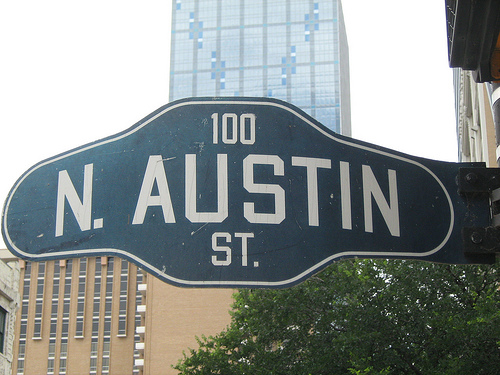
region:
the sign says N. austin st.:
[16, 97, 498, 299]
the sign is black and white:
[1, 88, 499, 313]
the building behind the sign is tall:
[153, 57, 374, 373]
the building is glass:
[161, 3, 371, 163]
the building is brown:
[8, 230, 253, 373]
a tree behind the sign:
[31, 90, 498, 372]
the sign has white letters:
[26, 106, 426, 306]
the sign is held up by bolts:
[439, 131, 499, 273]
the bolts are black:
[455, 160, 499, 267]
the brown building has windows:
[13, 236, 253, 373]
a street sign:
[10, 98, 488, 293]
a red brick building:
[9, 251, 245, 373]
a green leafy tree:
[189, 247, 497, 369]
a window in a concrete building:
[0, 302, 12, 353]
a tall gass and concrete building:
[166, 2, 353, 140]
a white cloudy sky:
[0, 2, 450, 161]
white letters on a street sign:
[37, 148, 410, 282]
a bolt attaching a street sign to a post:
[461, 222, 494, 255]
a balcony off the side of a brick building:
[133, 296, 148, 315]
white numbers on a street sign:
[194, 102, 271, 145]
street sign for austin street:
[1, 87, 463, 340]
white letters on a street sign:
[48, 149, 110, 246]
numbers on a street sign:
[201, 105, 266, 150]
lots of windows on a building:
[9, 260, 160, 372]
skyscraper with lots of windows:
[164, 9, 358, 97]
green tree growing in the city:
[216, 298, 440, 361]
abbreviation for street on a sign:
[198, 229, 264, 276]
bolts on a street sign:
[456, 160, 494, 270]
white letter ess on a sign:
[237, 150, 291, 228]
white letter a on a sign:
[126, 148, 177, 233]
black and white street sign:
[1, 94, 499, 289]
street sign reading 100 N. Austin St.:
[1, 95, 497, 290]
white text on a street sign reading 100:
[203, 107, 268, 147]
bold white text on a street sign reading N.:
[47, 162, 122, 244]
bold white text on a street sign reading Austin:
[128, 147, 411, 239]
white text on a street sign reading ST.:
[198, 224, 265, 272]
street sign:
[0, 98, 498, 293]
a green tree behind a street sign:
[175, 249, 499, 371]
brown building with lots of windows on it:
[13, 244, 237, 374]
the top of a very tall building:
[169, 1, 351, 133]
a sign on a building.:
[0, 93, 498, 287]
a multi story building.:
[3, 248, 326, 373]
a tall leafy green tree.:
[168, 248, 498, 373]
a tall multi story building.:
[167, 0, 356, 147]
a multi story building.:
[434, 3, 498, 161]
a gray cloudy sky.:
[2, 0, 457, 252]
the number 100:
[188, 97, 290, 147]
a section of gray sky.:
[346, 0, 459, 170]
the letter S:
[231, 146, 286, 232]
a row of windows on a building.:
[134, 276, 159, 373]